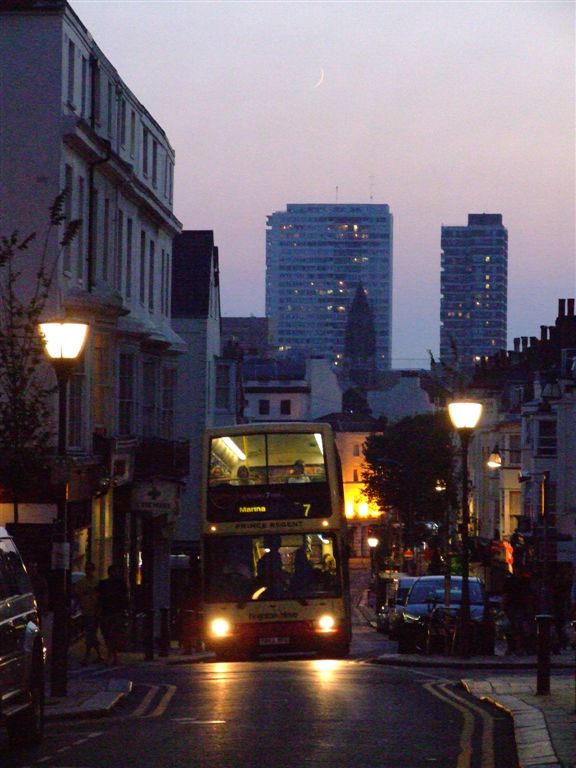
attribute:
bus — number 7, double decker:
[195, 417, 356, 664]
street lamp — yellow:
[445, 398, 486, 661]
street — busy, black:
[110, 656, 513, 767]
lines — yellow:
[420, 667, 498, 767]